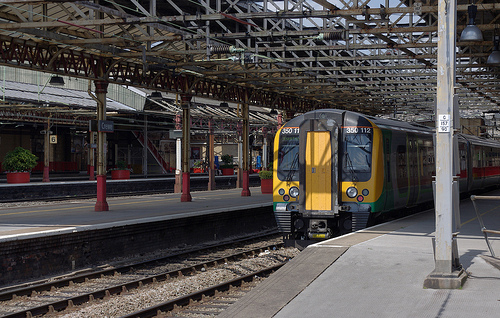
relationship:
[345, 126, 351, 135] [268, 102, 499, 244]
number on front of train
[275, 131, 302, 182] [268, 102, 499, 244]
window on front of train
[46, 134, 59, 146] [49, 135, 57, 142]
sign has number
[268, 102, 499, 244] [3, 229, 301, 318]
train on train tracks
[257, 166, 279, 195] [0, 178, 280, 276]
plant sitting on platform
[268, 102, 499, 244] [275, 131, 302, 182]
train has window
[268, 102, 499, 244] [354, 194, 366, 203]
train has light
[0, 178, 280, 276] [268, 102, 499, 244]
platform for train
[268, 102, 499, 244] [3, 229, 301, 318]
train riding on train tracks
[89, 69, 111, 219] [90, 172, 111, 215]
post has base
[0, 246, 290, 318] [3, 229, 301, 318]
gravel between train tracks